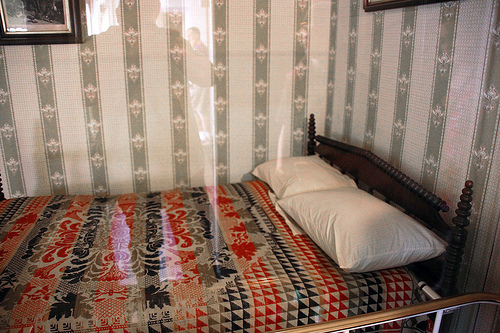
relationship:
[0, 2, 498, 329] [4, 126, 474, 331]
drape of bed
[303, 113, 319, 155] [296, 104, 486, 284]
post on bed frame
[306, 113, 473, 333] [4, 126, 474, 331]
bed frame on bed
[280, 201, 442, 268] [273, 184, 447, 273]
wrinkles on pillow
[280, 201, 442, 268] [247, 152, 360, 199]
wrinkles on pillow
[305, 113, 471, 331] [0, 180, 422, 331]
headboard on bed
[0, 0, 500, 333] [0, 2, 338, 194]
design on wallpaper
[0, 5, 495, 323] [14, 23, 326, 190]
design on wallpaper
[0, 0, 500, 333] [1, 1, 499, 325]
design on wallpaper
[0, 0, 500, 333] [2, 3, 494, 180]
design on wallpaper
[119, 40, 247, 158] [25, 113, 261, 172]
wallpaper on wall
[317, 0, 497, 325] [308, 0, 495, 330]
wallpaper on wall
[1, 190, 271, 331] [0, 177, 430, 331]
pattern on bedspread